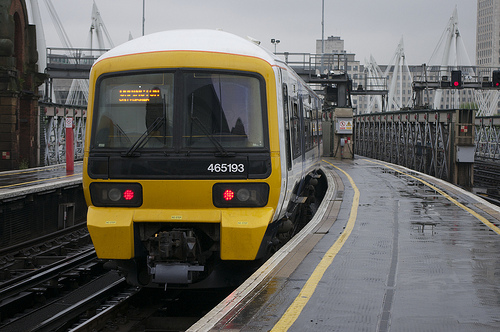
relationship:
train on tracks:
[85, 28, 327, 288] [5, 219, 189, 330]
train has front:
[85, 28, 327, 288] [84, 50, 277, 256]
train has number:
[85, 28, 327, 288] [206, 161, 245, 173]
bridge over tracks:
[41, 45, 482, 81] [5, 219, 189, 330]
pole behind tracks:
[64, 114, 73, 174] [5, 219, 189, 330]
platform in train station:
[0, 155, 82, 197] [4, 27, 499, 322]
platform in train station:
[233, 149, 494, 332] [4, 27, 499, 322]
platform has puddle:
[233, 149, 494, 332] [400, 180, 441, 201]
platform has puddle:
[233, 149, 494, 332] [412, 215, 440, 229]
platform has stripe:
[233, 149, 494, 332] [267, 161, 361, 330]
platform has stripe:
[233, 149, 494, 332] [368, 153, 500, 239]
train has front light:
[85, 28, 327, 288] [213, 181, 269, 207]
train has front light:
[85, 28, 327, 288] [89, 182, 143, 209]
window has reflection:
[93, 74, 264, 176] [100, 75, 250, 173]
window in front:
[93, 74, 264, 176] [84, 50, 277, 256]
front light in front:
[213, 181, 269, 207] [84, 50, 277, 256]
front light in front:
[89, 182, 143, 209] [84, 50, 277, 256]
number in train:
[206, 161, 245, 173] [85, 28, 327, 288]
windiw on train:
[292, 87, 313, 152] [85, 28, 327, 288]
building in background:
[473, 2, 499, 167] [418, 2, 497, 136]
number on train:
[206, 161, 245, 173] [85, 28, 327, 288]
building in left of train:
[473, 2, 499, 167] [85, 28, 327, 288]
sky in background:
[33, 4, 479, 56] [418, 2, 497, 136]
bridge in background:
[41, 45, 482, 81] [418, 2, 497, 136]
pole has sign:
[64, 114, 73, 174] [65, 117, 76, 129]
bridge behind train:
[41, 45, 482, 81] [85, 28, 327, 288]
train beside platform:
[85, 28, 327, 288] [233, 149, 494, 332]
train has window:
[85, 28, 327, 288] [93, 74, 264, 176]